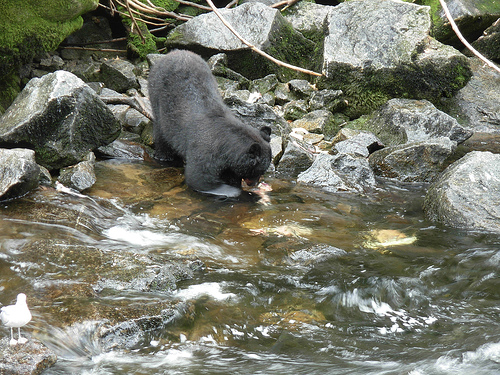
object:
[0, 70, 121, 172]
rock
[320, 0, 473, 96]
rock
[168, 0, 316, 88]
rock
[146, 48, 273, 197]
bear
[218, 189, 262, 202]
next meal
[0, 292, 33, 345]
bird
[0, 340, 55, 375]
stone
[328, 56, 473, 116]
moss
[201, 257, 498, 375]
water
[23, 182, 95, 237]
stone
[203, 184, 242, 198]
paws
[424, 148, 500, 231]
rocks